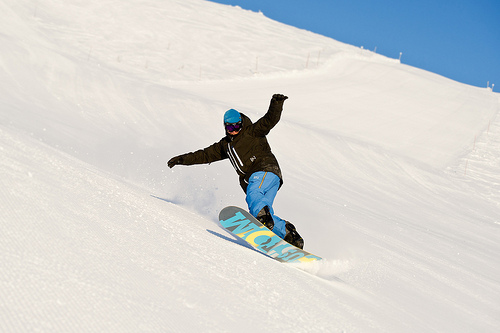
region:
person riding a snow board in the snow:
[149, 87, 334, 283]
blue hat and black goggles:
[220, 106, 247, 141]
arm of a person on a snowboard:
[255, 88, 289, 140]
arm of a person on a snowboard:
[163, 133, 230, 171]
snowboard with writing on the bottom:
[215, 202, 329, 274]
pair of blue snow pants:
[242, 168, 300, 236]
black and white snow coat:
[163, 91, 291, 195]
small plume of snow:
[278, 249, 364, 282]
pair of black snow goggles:
[220, 119, 246, 135]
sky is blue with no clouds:
[257, 0, 498, 90]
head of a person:
[209, 95, 246, 137]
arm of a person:
[165, 132, 235, 190]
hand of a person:
[162, 151, 190, 181]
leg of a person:
[243, 169, 300, 223]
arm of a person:
[249, 102, 290, 143]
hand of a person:
[265, 79, 303, 111]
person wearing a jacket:
[117, 53, 351, 251]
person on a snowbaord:
[130, 56, 374, 268]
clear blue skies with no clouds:
[397, 18, 482, 49]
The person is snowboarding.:
[226, 199, 310, 269]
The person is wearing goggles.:
[219, 114, 244, 136]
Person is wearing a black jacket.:
[197, 132, 284, 179]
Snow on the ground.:
[61, 213, 165, 323]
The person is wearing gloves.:
[271, 89, 293, 102]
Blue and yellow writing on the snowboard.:
[222, 211, 271, 250]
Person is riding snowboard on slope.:
[206, 167, 316, 275]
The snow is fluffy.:
[74, 27, 402, 109]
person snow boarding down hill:
[45, 14, 451, 315]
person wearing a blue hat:
[212, 58, 257, 149]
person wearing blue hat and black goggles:
[178, 43, 275, 165]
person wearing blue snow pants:
[123, 56, 363, 273]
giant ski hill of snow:
[33, 11, 498, 317]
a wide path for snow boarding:
[215, 19, 495, 281]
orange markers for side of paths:
[118, 22, 396, 102]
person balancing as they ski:
[136, 64, 392, 308]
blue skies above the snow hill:
[329, 2, 498, 120]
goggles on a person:
[225, 121, 247, 133]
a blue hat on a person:
[224, 108, 242, 122]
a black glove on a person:
[270, 93, 290, 105]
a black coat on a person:
[174, 100, 286, 196]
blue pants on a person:
[244, 170, 285, 237]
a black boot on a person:
[285, 222, 305, 248]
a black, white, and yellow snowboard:
[218, 202, 320, 269]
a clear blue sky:
[216, 1, 497, 94]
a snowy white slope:
[1, 2, 497, 331]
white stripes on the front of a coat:
[223, 140, 249, 179]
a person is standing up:
[162, 81, 307, 236]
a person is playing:
[165, 93, 305, 248]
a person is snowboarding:
[160, 86, 301, 242]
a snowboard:
[221, 204, 323, 272]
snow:
[5, 1, 497, 331]